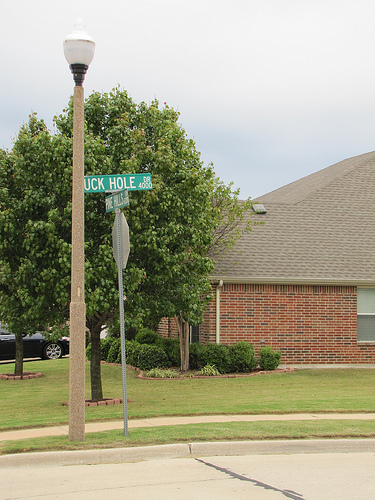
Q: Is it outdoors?
A: Yes, it is outdoors.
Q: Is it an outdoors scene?
A: Yes, it is outdoors.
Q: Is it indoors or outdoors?
A: It is outdoors.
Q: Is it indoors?
A: No, it is outdoors.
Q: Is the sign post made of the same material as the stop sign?
A: Yes, both the sign post and the stop sign are made of metal.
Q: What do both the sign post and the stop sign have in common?
A: The material, both the sign post and the stop sign are metallic.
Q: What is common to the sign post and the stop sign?
A: The material, both the sign post and the stop sign are metallic.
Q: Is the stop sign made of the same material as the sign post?
A: Yes, both the stop sign and the sign post are made of metal.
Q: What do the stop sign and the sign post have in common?
A: The material, both the stop sign and the sign post are metallic.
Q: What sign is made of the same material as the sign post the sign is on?
A: The stop sign is made of the same material as the sign post.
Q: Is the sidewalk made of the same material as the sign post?
A: No, the sidewalk is made of concrete and the sign post is made of metal.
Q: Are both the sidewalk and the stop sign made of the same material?
A: No, the sidewalk is made of cement and the stop sign is made of metal.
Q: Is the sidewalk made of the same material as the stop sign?
A: No, the sidewalk is made of cement and the stop sign is made of metal.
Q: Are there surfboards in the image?
A: No, there are no surfboards.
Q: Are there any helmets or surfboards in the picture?
A: No, there are no surfboards or helmets.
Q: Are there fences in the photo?
A: No, there are no fences.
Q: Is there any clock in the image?
A: No, there are no clocks.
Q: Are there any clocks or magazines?
A: No, there are no clocks or magazines.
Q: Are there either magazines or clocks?
A: No, there are no clocks or magazines.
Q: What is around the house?
A: The shrubs are around the house.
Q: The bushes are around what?
A: The bushes are around the house.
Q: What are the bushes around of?
A: The bushes are around the house.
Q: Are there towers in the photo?
A: No, there are no towers.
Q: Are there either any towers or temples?
A: No, there are no towers or temples.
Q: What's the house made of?
A: The house is made of brick.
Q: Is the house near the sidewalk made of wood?
A: No, the house is made of brick.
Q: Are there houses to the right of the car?
A: Yes, there is a house to the right of the car.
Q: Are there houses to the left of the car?
A: No, the house is to the right of the car.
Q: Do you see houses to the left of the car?
A: No, the house is to the right of the car.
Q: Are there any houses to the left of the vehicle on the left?
A: No, the house is to the right of the car.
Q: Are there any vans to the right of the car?
A: No, there is a house to the right of the car.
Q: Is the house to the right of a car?
A: Yes, the house is to the right of a car.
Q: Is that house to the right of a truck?
A: No, the house is to the right of a car.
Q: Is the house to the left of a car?
A: No, the house is to the right of a car.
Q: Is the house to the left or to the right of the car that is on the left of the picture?
A: The house is to the right of the car.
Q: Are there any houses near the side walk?
A: Yes, there is a house near the side walk.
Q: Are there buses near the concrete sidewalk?
A: No, there is a house near the side walk.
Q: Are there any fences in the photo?
A: No, there are no fences.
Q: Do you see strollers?
A: No, there are no strollers.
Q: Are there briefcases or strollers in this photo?
A: No, there are no strollers or briefcases.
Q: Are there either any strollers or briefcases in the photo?
A: No, there are no strollers or briefcases.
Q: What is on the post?
A: The streetlight is on the post.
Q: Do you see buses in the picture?
A: No, there are no buses.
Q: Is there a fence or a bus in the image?
A: No, there are no buses or fences.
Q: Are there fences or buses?
A: No, there are no buses or fences.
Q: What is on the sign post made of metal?
A: The sign is on the sign post.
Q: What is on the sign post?
A: The sign is on the sign post.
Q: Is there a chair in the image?
A: No, there are no chairs.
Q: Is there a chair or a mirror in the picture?
A: No, there are no chairs or mirrors.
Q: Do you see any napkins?
A: No, there are no napkins.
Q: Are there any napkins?
A: No, there are no napkins.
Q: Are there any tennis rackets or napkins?
A: No, there are no napkins or tennis rackets.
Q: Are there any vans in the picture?
A: No, there are no vans.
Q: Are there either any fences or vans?
A: No, there are no vans or fences.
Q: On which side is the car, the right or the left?
A: The car is on the left of the image.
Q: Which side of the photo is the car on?
A: The car is on the left of the image.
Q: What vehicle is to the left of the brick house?
A: The vehicle is a car.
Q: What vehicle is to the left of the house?
A: The vehicle is a car.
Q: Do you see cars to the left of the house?
A: Yes, there is a car to the left of the house.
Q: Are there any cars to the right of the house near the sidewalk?
A: No, the car is to the left of the house.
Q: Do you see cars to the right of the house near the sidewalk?
A: No, the car is to the left of the house.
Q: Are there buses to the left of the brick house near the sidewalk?
A: No, there is a car to the left of the house.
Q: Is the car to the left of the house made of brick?
A: Yes, the car is to the left of the house.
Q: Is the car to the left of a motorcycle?
A: No, the car is to the left of the house.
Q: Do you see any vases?
A: No, there are no vases.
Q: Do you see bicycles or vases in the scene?
A: No, there are no vases or bicycles.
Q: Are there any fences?
A: No, there are no fences.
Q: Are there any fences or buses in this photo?
A: No, there are no fences or buses.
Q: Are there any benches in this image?
A: No, there are no benches.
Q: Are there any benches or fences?
A: No, there are no benches or fences.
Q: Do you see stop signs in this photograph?
A: Yes, there is a stop sign.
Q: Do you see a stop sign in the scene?
A: Yes, there is a stop sign.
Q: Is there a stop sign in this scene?
A: Yes, there is a stop sign.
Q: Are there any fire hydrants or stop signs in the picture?
A: Yes, there is a stop sign.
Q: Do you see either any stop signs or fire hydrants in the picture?
A: Yes, there is a stop sign.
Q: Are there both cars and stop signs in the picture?
A: Yes, there are both a stop sign and a car.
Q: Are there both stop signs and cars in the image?
A: Yes, there are both a stop sign and a car.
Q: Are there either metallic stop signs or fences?
A: Yes, there is a metal stop sign.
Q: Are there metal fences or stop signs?
A: Yes, there is a metal stop sign.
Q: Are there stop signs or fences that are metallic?
A: Yes, the stop sign is metallic.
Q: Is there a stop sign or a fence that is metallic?
A: Yes, the stop sign is metallic.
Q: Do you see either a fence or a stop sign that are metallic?
A: Yes, the stop sign is metallic.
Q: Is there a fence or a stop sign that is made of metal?
A: Yes, the stop sign is made of metal.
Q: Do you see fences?
A: No, there are no fences.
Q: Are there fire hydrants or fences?
A: No, there are no fences or fire hydrants.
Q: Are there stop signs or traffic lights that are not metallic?
A: No, there is a stop sign but it is metallic.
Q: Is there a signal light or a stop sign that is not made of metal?
A: No, there is a stop sign but it is made of metal.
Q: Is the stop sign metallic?
A: Yes, the stop sign is metallic.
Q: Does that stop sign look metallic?
A: Yes, the stop sign is metallic.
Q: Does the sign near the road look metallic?
A: Yes, the stop sign is metallic.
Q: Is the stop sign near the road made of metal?
A: Yes, the stop sign is made of metal.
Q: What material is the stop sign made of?
A: The stop sign is made of metal.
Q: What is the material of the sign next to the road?
A: The stop sign is made of metal.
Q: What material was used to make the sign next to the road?
A: The stop sign is made of metal.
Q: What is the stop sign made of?
A: The stop sign is made of metal.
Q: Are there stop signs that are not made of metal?
A: No, there is a stop sign but it is made of metal.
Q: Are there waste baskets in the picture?
A: No, there are no waste baskets.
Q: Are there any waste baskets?
A: No, there are no waste baskets.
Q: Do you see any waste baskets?
A: No, there are no waste baskets.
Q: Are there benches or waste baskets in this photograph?
A: No, there are no waste baskets or benches.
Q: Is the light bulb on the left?
A: Yes, the light bulb is on the left of the image.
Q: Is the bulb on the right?
A: No, the bulb is on the left of the image.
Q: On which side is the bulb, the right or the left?
A: The bulb is on the left of the image.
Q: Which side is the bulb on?
A: The bulb is on the left of the image.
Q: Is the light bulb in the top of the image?
A: Yes, the light bulb is in the top of the image.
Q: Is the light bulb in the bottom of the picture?
A: No, the light bulb is in the top of the image.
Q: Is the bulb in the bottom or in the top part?
A: The bulb is in the top of the image.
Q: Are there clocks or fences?
A: No, there are no fences or clocks.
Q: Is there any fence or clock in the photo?
A: No, there are no fences or clocks.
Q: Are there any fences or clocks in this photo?
A: No, there are no fences or clocks.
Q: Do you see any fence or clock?
A: No, there are no fences or clocks.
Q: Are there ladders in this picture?
A: No, there are no ladders.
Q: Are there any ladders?
A: No, there are no ladders.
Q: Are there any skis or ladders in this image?
A: No, there are no ladders or skis.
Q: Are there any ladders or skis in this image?
A: No, there are no ladders or skis.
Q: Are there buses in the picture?
A: No, there are no buses.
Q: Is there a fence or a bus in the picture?
A: No, there are no buses or fences.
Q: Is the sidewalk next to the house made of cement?
A: Yes, the sidewalk is made of cement.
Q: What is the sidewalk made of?
A: The sidewalk is made of concrete.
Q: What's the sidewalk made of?
A: The sidewalk is made of concrete.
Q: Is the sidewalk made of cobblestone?
A: No, the sidewalk is made of cement.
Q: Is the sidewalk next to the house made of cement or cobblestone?
A: The sidewalk is made of cement.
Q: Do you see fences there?
A: No, there are no fences.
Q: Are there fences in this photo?
A: No, there are no fences.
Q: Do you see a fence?
A: No, there are no fences.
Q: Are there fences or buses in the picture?
A: No, there are no fences or buses.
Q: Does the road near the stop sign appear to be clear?
A: Yes, the road is clear.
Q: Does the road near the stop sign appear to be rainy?
A: No, the road is clear.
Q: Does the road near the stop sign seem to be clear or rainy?
A: The road is clear.